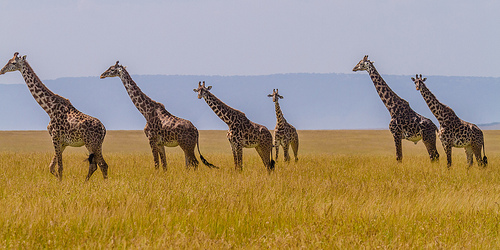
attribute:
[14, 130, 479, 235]
grass — VERY DRY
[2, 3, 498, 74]
sky — purplish 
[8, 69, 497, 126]
mountains — blue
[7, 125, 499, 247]
grass — green, yellow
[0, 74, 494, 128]
hills — grey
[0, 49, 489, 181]
giraffes — tall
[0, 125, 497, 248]
field — grassy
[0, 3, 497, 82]
sky — white, hazy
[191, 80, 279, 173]
giraffe — black, cream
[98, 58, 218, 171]
giraffe — black, cream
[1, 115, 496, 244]
field — grassy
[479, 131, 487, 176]
tail — long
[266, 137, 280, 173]
tail — long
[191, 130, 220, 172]
tail — long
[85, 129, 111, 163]
tail — long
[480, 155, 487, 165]
tip — black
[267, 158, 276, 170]
tip — black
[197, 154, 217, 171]
tip — black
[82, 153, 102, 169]
tip — black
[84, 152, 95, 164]
tail — black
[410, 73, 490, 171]
giraffe — black, cream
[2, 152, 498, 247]
field — grassy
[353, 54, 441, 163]
giraffe — black, cream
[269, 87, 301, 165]
giraffe — black, cream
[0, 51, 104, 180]
giraffe — black, cream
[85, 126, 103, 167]
tail — long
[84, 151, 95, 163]
tip — black